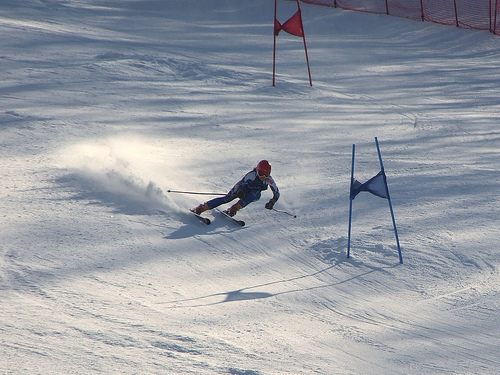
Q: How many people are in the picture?
A: One.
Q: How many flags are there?
A: Two.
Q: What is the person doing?
A: Skiing.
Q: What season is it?
A: Winter.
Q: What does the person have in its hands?
A: Ski poles.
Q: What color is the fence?
A: Orange.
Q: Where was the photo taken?
A: In the snow.